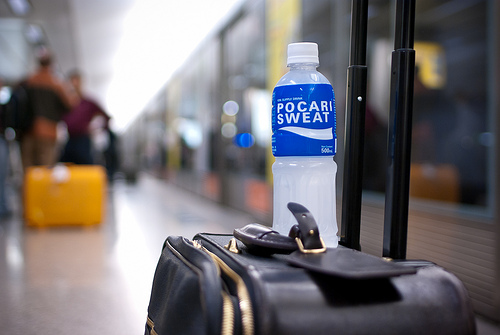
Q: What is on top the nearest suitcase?
A: Bottle.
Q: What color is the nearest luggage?
A: Black.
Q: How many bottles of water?
A: One.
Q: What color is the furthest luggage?
A: Yellow.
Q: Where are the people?
A: Behind the suitcase.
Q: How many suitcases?
A: Two.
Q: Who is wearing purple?
A: The woman.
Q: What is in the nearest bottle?
A: Water.